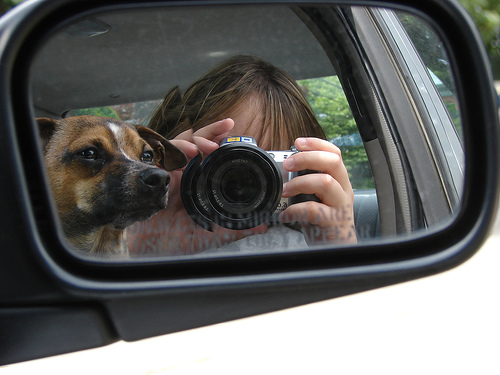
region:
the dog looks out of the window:
[36, 118, 173, 254]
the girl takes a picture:
[184, 137, 299, 227]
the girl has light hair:
[165, 62, 332, 157]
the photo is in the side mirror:
[6, 0, 498, 299]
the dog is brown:
[36, 119, 181, 258]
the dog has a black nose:
[143, 167, 172, 194]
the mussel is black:
[106, 160, 166, 217]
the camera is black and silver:
[195, 137, 292, 221]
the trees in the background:
[62, 71, 456, 189]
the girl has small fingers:
[177, 122, 354, 242]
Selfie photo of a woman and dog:
[5, 1, 487, 321]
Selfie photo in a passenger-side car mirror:
[20, 14, 470, 295]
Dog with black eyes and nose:
[45, 107, 194, 232]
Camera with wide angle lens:
[172, 70, 363, 232]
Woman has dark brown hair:
[141, 30, 377, 240]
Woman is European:
[131, 53, 372, 250]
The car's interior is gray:
[52, 15, 468, 261]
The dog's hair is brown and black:
[55, 105, 181, 230]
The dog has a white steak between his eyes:
[93, 106, 143, 206]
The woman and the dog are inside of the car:
[36, 9, 448, 289]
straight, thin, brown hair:
[198, 57, 322, 137]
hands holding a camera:
[149, 131, 344, 243]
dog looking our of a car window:
[11, 106, 191, 256]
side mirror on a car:
[0, 0, 497, 296]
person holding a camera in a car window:
[110, 49, 365, 246]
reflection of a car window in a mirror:
[31, 3, 433, 280]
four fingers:
[272, 134, 342, 242]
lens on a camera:
[198, 144, 283, 233]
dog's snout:
[101, 156, 183, 227]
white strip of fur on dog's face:
[92, 107, 157, 202]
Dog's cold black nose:
[131, 165, 179, 193]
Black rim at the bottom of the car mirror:
[148, 260, 243, 276]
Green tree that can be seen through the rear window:
[310, 80, 340, 115]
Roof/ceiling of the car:
[117, 20, 227, 60]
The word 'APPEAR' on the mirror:
[292, 222, 373, 242]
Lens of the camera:
[221, 166, 258, 203]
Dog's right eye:
[68, 138, 108, 164]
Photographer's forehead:
[235, 105, 270, 136]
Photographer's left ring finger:
[281, 171, 347, 206]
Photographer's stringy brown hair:
[251, 52, 310, 133]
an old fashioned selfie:
[134, 49, 365, 261]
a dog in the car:
[5, 106, 198, 261]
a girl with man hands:
[153, 53, 350, 254]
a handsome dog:
[35, 110, 180, 232]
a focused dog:
[40, 105, 182, 230]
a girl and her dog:
[32, 46, 358, 254]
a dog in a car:
[18, 95, 188, 281]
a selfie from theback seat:
[30, 31, 405, 297]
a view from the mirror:
[0, 0, 498, 321]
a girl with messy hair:
[125, 53, 361, 263]